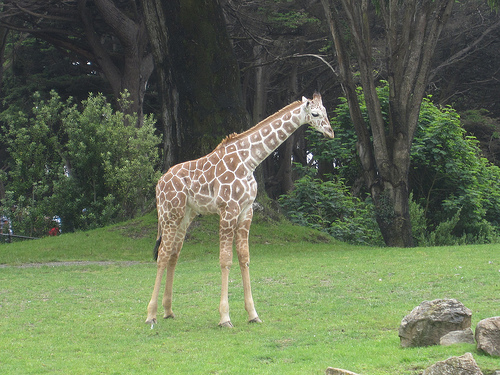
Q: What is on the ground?
A: Stones.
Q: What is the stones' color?
A: Gray.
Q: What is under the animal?
A: Grass.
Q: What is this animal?
A: Giraffe.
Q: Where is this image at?
A: Park.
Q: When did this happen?
A: During the day time.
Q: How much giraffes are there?
A: One.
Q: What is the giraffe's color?
A: White and brown.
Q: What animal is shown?
A: Giraffe.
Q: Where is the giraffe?
A: In a preserve.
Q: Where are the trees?
A: Behind the giraffe.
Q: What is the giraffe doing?
A: Standing.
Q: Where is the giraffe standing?
A: On the grass.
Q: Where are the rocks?
A: Beside the giraffe.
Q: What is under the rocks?
A: The ground.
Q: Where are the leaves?
A: On the trees.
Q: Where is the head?
A: On the giraffe.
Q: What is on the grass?
A: A rock.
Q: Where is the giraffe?
A: In the park.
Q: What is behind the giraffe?
A: A tree.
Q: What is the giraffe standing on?
A: Grass.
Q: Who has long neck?
A: A giraffe.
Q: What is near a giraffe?
A: A bush.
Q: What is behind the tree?
A: A bush.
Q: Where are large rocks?
A: On the grass.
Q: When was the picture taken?
A: Daytime.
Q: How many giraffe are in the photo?
A: One.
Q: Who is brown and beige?
A: A giraffe.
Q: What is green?
A: Grass.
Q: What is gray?
A: Rocks.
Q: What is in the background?
A: Trees.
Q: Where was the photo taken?
A: At a zoo.